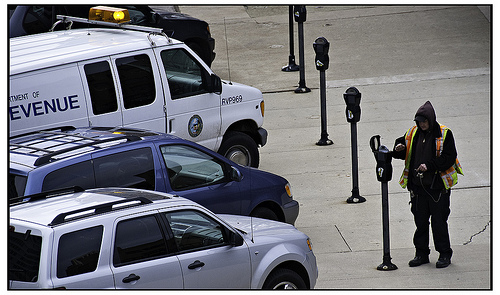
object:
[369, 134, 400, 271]
meter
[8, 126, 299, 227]
van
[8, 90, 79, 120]
text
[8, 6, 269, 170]
van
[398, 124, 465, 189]
vest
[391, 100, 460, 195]
hoodie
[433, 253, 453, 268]
shoes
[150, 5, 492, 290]
sidewalk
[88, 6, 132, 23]
light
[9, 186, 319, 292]
vehicle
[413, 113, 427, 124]
cap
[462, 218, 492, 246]
crack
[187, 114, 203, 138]
emblem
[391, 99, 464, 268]
man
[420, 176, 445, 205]
chain